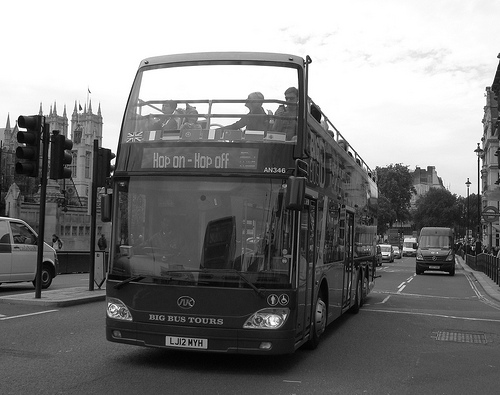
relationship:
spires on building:
[45, 83, 111, 126] [34, 110, 109, 199]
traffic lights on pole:
[4, 112, 78, 199] [16, 167, 65, 316]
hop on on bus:
[155, 148, 185, 166] [100, 36, 386, 367]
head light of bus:
[243, 309, 292, 330] [100, 36, 386, 367]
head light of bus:
[100, 294, 139, 319] [100, 36, 386, 367]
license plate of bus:
[163, 330, 213, 347] [100, 36, 386, 367]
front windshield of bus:
[115, 156, 289, 294] [100, 36, 386, 367]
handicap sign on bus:
[275, 287, 294, 303] [85, 50, 409, 358]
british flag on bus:
[125, 122, 140, 136] [100, 36, 386, 367]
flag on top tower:
[75, 90, 97, 107] [72, 76, 111, 207]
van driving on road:
[406, 221, 456, 283] [332, 270, 496, 380]